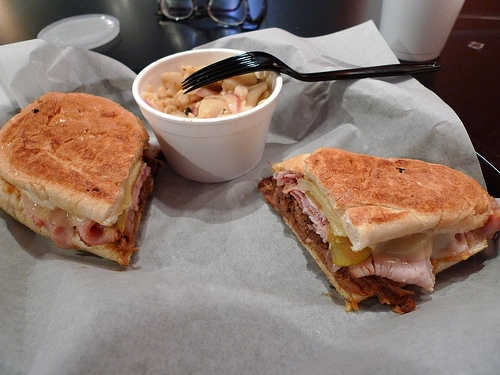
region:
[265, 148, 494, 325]
a ham and cheese with egg panini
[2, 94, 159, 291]
a ham and cheese with egg panini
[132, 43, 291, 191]
a small styrofoam cup of salad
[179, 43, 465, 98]
a black plastic fork on top of the salad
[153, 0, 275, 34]
a pair of eyeglasses on the table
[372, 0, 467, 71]
a styrofoam beverage cup behind the food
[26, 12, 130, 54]
a white plastic lid for the beverage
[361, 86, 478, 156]
white paper in the basket the food is in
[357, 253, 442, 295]
some cooked ham on the sandwich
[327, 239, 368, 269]
egg yolk in the sandwich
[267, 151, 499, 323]
Ham and cheese sandwich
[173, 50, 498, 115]
Black plastic fork on side of bowl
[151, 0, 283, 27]
A pair of glasses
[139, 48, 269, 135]
Pasta salad in white bowl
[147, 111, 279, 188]
White sterifoam cup on table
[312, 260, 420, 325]
Slices of bacon in sandwich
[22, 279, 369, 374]
White paper on table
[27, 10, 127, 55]
White plastic on table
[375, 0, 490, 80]
White cup with drink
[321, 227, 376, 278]
Yellow vegetable in sandwich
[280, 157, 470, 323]
the sandwhich has bacon on it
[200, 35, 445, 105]
the spoon is black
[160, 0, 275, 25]
there are glasses on the table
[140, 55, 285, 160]
the cup is full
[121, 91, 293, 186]
the cup is white in color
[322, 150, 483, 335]
the bread has a brown surface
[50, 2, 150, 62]
there is a plastic lid on the table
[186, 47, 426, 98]
the fork is black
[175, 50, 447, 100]
the fork is made of plastic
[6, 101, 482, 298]
there are two sand whiches on the table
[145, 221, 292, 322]
the paper is translucent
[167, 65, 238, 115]
the salad is in a cup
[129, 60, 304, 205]
the cup is white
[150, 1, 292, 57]
eyeglasses on the table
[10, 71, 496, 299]
two sandwiches on the paper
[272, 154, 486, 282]
the bread is toasted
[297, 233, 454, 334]
ham between the bread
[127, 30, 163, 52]
the table is black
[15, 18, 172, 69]
the lid is on the table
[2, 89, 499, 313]
The sandwich is cut in two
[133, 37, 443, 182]
The fork is on cup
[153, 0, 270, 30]
eyeglasses are on the table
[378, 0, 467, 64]
Styrofoam cup is on right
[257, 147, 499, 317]
Sandwich is on the right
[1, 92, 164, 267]
Sandwich is on left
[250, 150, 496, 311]
Sandwich has several meats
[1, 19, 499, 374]
Food is on paper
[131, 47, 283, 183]
Macaroni salad is in cup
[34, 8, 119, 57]
Lid is made of plastic